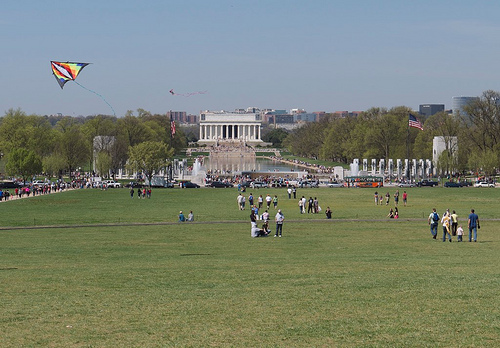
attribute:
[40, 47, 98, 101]
kite — flying, patterned, colorful, blue, here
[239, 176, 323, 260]
people — lot, together, walking, wearing, standing, infront, grouped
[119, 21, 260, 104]
sky — clear, blue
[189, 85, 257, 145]
building — white, capitol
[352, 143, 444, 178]
feature — water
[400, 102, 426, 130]
flag — flying, background, waving, american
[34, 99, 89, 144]
trees — background, green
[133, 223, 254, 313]
lawn — grassy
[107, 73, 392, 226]
mall — dc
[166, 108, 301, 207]
memorial — white, looking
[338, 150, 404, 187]
fountains — spraying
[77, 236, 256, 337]
grass — green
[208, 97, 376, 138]
skyline — city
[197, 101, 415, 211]
landmark — famous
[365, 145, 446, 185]
fountain — spraying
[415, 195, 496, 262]
crowd — walking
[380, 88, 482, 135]
high rises — distant